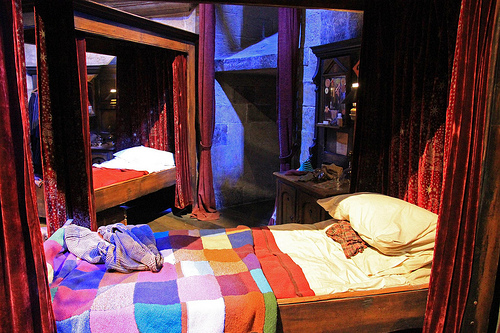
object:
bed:
[40, 191, 439, 332]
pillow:
[113, 145, 176, 168]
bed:
[33, 145, 177, 217]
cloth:
[325, 220, 368, 259]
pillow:
[317, 191, 439, 256]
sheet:
[268, 223, 436, 296]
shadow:
[317, 188, 372, 217]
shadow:
[268, 219, 337, 230]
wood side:
[277, 283, 429, 332]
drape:
[189, 0, 223, 221]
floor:
[128, 200, 275, 233]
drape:
[356, 1, 500, 333]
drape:
[114, 54, 193, 209]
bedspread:
[43, 222, 279, 333]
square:
[134, 302, 182, 333]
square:
[223, 292, 266, 333]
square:
[186, 297, 226, 333]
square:
[176, 274, 223, 303]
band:
[279, 142, 300, 164]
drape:
[268, 6, 308, 227]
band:
[200, 141, 212, 152]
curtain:
[0, 0, 67, 333]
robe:
[64, 223, 164, 273]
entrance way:
[209, 3, 279, 219]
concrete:
[211, 0, 279, 211]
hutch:
[308, 37, 364, 178]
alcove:
[33, 0, 198, 231]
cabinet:
[85, 64, 117, 164]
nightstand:
[273, 172, 351, 225]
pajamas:
[34, 174, 43, 188]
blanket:
[92, 166, 149, 190]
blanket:
[251, 225, 316, 298]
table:
[91, 129, 141, 164]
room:
[0, 0, 500, 333]